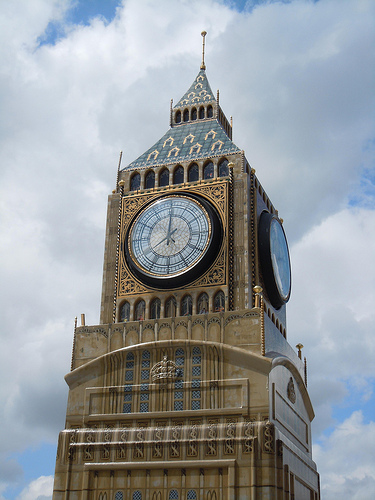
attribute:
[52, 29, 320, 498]
building — tall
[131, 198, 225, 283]
clock — white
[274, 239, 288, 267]
dials — metal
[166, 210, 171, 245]
dial — black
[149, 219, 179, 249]
dial — black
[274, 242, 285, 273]
dials — black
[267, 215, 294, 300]
cover — glass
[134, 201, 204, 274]
clock face — white